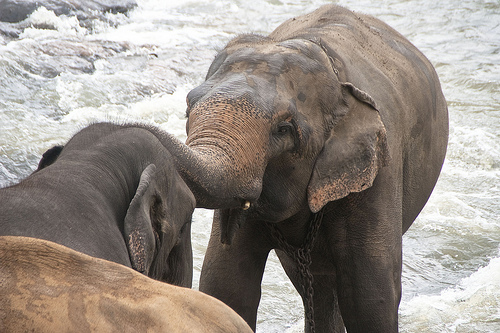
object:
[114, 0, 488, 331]
elephant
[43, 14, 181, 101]
ground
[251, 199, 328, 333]
chain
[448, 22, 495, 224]
water